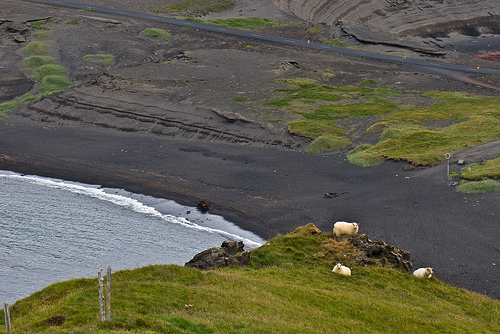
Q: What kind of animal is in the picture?
A: Sheep.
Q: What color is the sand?
A: Black.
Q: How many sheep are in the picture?
A: Three.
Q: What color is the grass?
A: Green.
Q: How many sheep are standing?
A: One.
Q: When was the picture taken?
A: Daytime.